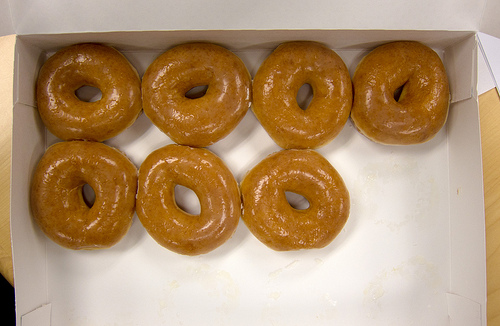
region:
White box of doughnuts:
[1, 0, 498, 325]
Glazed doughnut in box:
[30, 41, 142, 143]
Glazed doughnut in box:
[138, 40, 251, 147]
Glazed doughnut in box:
[250, 40, 354, 150]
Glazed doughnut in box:
[351, 40, 449, 145]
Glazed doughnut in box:
[28, 139, 136, 249]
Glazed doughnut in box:
[135, 143, 243, 257]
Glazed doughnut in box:
[240, 146, 350, 254]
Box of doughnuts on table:
[0, 2, 499, 324]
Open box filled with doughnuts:
[0, 1, 498, 324]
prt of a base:
[353, 249, 388, 305]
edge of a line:
[290, 188, 310, 200]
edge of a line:
[216, 212, 254, 272]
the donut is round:
[37, 43, 141, 136]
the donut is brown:
[142, 39, 250, 141]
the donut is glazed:
[251, 43, 352, 150]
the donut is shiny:
[350, 40, 448, 144]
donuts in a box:
[15, 34, 485, 324]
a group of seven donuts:
[39, 40, 446, 252]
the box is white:
[13, 33, 489, 324]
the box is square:
[14, 33, 486, 325]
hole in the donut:
[172, 180, 205, 214]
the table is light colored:
[2, 34, 499, 324]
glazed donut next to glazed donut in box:
[34, 40, 141, 144]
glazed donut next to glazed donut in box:
[27, 140, 136, 251]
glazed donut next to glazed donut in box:
[140, 42, 252, 150]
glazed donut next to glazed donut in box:
[134, 142, 241, 256]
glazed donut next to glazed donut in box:
[253, 42, 350, 147]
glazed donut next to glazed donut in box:
[239, 149, 347, 249]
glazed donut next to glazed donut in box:
[350, 41, 450, 146]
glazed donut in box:
[137, 144, 237, 255]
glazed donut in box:
[241, 147, 351, 251]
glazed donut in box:
[31, 142, 136, 250]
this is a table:
[485, 160, 498, 177]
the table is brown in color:
[480, 124, 497, 143]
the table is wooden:
[483, 97, 495, 125]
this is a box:
[375, 206, 461, 296]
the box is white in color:
[436, 188, 472, 245]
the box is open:
[60, 261, 182, 308]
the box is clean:
[133, 277, 165, 299]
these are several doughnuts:
[40, 41, 427, 257]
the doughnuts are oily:
[119, 79, 299, 243]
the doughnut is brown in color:
[251, 179, 273, 215]